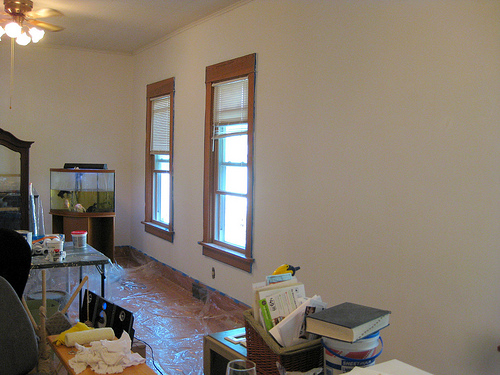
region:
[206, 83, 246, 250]
a double hung window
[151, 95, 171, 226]
a double hung window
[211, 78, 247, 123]
a white venetian blind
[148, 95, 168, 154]
a white venetian blind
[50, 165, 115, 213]
a large fish aquarium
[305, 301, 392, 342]
a black hardback book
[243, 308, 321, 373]
a brown wicker basket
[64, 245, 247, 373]
a clear plastic tarp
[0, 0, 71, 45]
a ceiling fan with light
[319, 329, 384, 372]
a white bucket with blue handle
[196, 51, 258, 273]
A wood framed window.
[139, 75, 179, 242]
A window in a house.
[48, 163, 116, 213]
A large fish tank.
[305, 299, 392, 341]
A blue colored book.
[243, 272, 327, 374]
A basket of papers.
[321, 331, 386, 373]
White orange and blue bucket.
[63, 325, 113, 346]
A yellow paint roller.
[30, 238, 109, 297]
A dark colored table.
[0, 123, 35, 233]
A large wood framed mirror.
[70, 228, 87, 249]
Small red and white bucket.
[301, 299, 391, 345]
a large book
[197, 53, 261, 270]
a large brown window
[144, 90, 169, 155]
white window blinds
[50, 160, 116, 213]
a large fish tank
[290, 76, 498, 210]
part of a painted white wall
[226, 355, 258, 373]
part of a glass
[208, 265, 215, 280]
a wall outlet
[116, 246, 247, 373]
clear plastic floor wrap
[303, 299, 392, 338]
Large gray book on the bucket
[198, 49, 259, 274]
First window in the room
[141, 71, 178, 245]
Second window in the room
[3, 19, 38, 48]
Four lights on the fan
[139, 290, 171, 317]
Small patch of the waxed floor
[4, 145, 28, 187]
Mirror in the room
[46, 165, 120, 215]
Large fish tank in the house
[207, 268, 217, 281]
Outlet plug hooked on the wall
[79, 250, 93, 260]
Small part of the waxed table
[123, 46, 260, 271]
two wood trimmed rectangular windows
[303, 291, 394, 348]
one thick book with dark cover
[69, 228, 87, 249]
little cylindrical plastic container with red lid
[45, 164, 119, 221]
one fish tank with green water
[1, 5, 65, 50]
one illuminated ceiling fan light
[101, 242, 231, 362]
section of clear plastic painting drop cloth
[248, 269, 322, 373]
group of papers in woven basket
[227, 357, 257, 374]
rounded top of clear glass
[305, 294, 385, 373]
book on top of little plastic tub